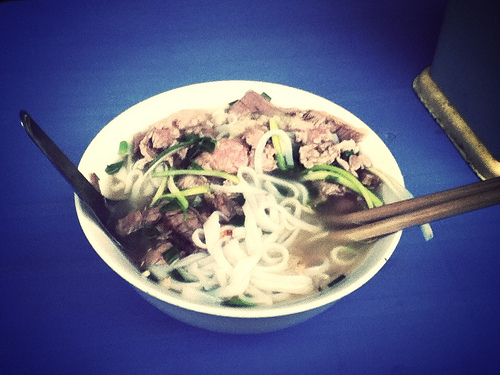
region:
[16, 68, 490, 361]
blue painted surface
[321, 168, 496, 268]
a pair of wooden chopsticks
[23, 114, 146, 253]
metal spoon in bowl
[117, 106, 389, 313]
white noodles in broth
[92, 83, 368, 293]
soup with broth and meat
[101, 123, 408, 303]
bowl of soup with greens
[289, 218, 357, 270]
light clear broth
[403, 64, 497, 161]
dirty white edging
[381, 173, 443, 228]
food hanging over edge of bowl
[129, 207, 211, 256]
meat with grill stripes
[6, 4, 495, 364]
a white bowl on a blue table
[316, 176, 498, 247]
a pair of chopsticks are in the bowl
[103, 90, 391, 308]
the bowl is to the brim with food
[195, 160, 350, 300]
white noodles in a sauce is in the bowl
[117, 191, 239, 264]
a dark meat is next the noodles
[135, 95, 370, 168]
a light colored meat is on top of the bowl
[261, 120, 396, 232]
green scallions are in the bowl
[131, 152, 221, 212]
thinned sliced cucumbers are in the dish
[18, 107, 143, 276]
a black spoon is in the side of thedish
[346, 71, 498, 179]
a metallic object is on the table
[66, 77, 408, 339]
A white bowl full of food.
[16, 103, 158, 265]
A black spoon in a bowl full of food.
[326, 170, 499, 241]
black chopsticks in a bowl of food.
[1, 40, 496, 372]
A blue table cloth.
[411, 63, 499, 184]
Tarnished brass metal piece.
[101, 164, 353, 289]
A bunch of noodles in a bowl.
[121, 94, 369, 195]
Meat on top of noodles.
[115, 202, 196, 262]
Meat in the spoon.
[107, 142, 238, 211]
Leeks on top of noodles.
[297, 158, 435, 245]
Leeks by the chopsticks.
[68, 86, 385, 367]
Food is in white bowl.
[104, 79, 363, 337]
White bowl is round in shape.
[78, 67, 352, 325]
White bowl is sitting on blue table.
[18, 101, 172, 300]
Black ladle in white bowl.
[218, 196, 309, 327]
White noodles in white bowl.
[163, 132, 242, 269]
Green vegetable in white bowl.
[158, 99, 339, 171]
Light brown food in bowl.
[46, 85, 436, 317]
Food is inside bowl.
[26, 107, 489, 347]
table is bright blue.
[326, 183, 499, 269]
Utensil on side of bowl.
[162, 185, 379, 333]
Noodles in broth in a bowl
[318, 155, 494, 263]
Chopsticks in the broth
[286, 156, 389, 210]
Green onions flavor food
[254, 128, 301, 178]
A noodle curls up over the meat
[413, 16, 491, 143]
White trim at the bottom of a blue wall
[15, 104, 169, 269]
A black spoon buried under the meat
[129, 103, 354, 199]
Meat fills half a bowl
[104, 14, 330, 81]
A blue surface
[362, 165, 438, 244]
A noodle sticking out of the bowl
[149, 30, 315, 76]
Light reflects off the surface